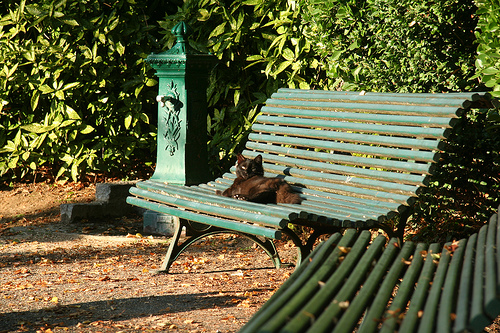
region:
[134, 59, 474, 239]
this is a bench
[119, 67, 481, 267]
the bench is green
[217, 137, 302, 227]
this is a cat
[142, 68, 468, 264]
a cat laying on a bench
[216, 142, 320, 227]
the cat is black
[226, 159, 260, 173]
cat has light eyes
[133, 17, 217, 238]
decorative pillar next to bench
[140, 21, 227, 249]
decorative pillar is green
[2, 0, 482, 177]
green bushes next to bench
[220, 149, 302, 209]
Black cat resting on a bench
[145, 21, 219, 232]
Green post next to the bench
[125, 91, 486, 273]
Green bench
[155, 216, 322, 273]
Legs of the green bench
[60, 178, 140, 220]
Cement blocks on the ground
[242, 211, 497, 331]
Bench next to the cat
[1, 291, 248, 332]
Shadow on the ground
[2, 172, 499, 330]
Ground with dirt and leaves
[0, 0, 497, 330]
Public bench area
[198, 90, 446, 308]
green bench near bushes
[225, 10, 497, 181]
green and leafy bushes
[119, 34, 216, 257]
green monument near bench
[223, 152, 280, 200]
cat lying on bench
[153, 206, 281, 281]
dark green legs on bench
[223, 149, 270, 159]
cat has black ears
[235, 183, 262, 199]
cat has black paws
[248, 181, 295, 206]
cat has black tail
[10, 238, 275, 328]
brown leaves on ground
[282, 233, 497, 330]
green and empty bench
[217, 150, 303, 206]
Brown and black cat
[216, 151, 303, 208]
Brown cat laying on a bench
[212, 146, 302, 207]
Brown cat relaxing on a bench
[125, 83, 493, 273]
Green wood bench with metal legs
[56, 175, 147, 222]
Cement bricks on the ground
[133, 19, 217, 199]
Green decorative statue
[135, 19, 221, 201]
Short green decorative pillar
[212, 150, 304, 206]
Cat falling asleep on a bench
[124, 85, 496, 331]
Two green wood park benches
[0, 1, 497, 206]
Bushed with green leaves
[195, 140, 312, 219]
A cat lounging on a green bench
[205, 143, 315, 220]
A cat lounging on a green bench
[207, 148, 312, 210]
A cat lounging on a green bench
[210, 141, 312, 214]
A cat lounging on a green bench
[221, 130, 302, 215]
black cat on green bench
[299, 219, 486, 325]
green bench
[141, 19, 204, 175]
green post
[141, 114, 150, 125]
a leaf on a stem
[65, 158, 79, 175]
a leaf on a stem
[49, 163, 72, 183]
a leaf on a stem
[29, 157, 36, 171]
a leaf on a stem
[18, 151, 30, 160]
a leaf on a stem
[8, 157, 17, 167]
a leaf on a stem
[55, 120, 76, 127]
a leaf on a stem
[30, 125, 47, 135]
a leaf on a stem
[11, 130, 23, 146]
a leaf on a stem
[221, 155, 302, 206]
black cat laying on bench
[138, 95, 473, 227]
painted green wooden bench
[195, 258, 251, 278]
shadow of benches leg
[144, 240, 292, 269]
metal legs of green bench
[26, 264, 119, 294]
leaves covering the ground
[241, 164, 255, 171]
black cats yellow eyes